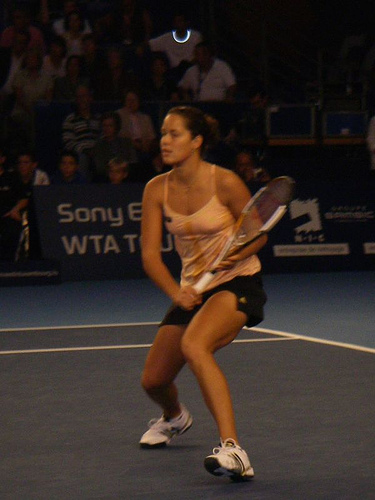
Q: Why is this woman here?
A: To play tennis.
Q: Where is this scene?
A: Tennis court.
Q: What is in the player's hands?
A: Tennis racquet.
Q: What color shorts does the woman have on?
A: Black.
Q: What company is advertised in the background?
A: Sony.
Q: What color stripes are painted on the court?
A: White.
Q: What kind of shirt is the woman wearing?
A: Tank top.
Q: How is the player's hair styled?
A: In a ponytail.